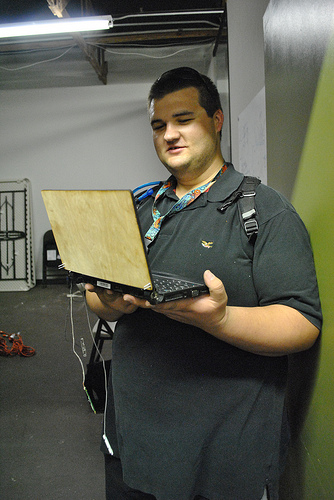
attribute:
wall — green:
[263, 2, 334, 497]